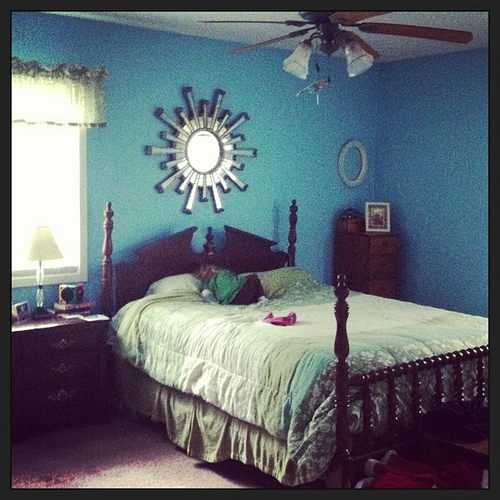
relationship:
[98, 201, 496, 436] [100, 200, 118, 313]
bed with post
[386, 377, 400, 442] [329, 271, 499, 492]
post on footboard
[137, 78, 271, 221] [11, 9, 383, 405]
mirror on wall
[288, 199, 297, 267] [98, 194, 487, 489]
post on bed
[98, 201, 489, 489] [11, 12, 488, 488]
bed in bedroom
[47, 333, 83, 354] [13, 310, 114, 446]
handle on dresser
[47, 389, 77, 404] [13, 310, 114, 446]
handle on dresser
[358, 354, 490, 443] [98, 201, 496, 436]
railing on bed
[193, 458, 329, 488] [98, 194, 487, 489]
shadow under bed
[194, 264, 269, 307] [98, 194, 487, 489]
child sleeping on bed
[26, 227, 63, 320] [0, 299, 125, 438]
lamp on night stand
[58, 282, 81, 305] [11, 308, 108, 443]
clock on night stand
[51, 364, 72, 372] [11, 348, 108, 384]
handle on drawer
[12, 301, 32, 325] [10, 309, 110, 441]
picture on nightstand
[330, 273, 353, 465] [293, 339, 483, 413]
post on footboard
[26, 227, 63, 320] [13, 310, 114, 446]
lamp on dresser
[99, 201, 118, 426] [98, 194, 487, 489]
post on bed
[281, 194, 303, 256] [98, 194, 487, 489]
post in corner of bed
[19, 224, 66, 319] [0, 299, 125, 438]
lamp on night stand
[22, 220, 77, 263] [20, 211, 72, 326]
lamp shade on lamp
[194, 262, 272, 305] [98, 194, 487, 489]
child on bed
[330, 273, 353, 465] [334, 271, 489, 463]
post on footboard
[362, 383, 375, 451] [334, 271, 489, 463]
post on footboard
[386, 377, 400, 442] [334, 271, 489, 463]
post on footboard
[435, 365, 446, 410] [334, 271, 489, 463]
post on footboard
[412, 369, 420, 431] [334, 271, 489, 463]
post on footboard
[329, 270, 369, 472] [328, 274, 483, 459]
post on footboard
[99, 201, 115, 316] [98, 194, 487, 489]
post on bed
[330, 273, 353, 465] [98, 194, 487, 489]
post on bed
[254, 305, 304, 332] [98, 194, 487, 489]
clothing on bed